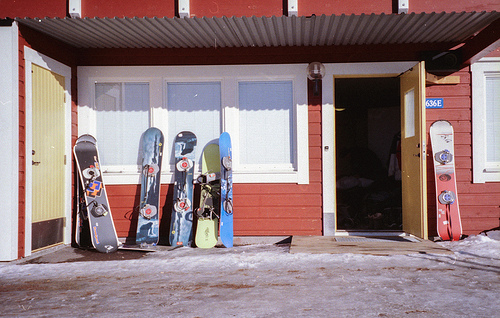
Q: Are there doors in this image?
A: Yes, there is a door.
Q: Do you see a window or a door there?
A: Yes, there is a door.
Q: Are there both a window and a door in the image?
A: Yes, there are both a door and a window.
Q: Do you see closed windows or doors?
A: Yes, there is a closed door.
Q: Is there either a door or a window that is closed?
A: Yes, the door is closed.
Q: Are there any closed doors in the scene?
A: Yes, there is a closed door.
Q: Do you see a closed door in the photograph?
A: Yes, there is a closed door.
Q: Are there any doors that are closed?
A: Yes, there is a door that is closed.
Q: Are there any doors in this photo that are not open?
A: Yes, there is an closed door.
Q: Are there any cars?
A: No, there are no cars.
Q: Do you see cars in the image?
A: No, there are no cars.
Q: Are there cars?
A: No, there are no cars.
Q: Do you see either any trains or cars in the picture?
A: No, there are no cars or trains.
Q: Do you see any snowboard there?
A: Yes, there is a snowboard.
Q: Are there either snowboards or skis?
A: Yes, there is a snowboard.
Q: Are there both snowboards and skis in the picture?
A: No, there is a snowboard but no skis.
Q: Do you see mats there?
A: No, there are no mats.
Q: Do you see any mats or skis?
A: No, there are no mats or skis.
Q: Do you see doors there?
A: Yes, there is a door.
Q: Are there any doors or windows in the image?
A: Yes, there is a door.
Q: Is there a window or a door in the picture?
A: Yes, there is a door.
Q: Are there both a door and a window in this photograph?
A: Yes, there are both a door and a window.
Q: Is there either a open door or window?
A: Yes, there is an open door.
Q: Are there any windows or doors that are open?
A: Yes, the door is open.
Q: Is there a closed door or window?
A: Yes, there is a closed door.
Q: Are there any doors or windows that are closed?
A: Yes, the door is closed.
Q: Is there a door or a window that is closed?
A: Yes, the door is closed.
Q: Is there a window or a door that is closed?
A: Yes, the door is closed.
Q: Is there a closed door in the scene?
A: Yes, there is a closed door.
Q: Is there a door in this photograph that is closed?
A: Yes, there is a door that is closed.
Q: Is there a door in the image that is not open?
A: Yes, there is an closed door.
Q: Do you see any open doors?
A: Yes, there is an open door.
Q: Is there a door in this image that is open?
A: Yes, there is a door that is open.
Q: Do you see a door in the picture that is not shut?
A: Yes, there is a open door.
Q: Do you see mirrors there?
A: No, there are no mirrors.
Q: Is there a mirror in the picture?
A: No, there are no mirrors.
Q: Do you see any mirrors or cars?
A: No, there are no mirrors or cars.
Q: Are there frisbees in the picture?
A: No, there are no frisbees.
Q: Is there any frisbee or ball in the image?
A: No, there are no frisbees or balls.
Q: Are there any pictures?
A: No, there are no pictures.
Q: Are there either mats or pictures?
A: No, there are no pictures or mats.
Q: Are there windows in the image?
A: Yes, there are windows.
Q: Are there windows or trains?
A: Yes, there are windows.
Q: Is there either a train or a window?
A: Yes, there are windows.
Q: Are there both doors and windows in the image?
A: Yes, there are both windows and a door.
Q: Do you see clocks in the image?
A: No, there are no clocks.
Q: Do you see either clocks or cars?
A: No, there are no clocks or cars.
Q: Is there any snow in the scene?
A: Yes, there is snow.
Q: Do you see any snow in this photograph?
A: Yes, there is snow.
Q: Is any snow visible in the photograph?
A: Yes, there is snow.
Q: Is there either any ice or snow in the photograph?
A: Yes, there is snow.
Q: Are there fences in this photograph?
A: No, there are no fences.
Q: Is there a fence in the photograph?
A: No, there are no fences.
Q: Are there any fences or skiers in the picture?
A: No, there are no fences or skiers.